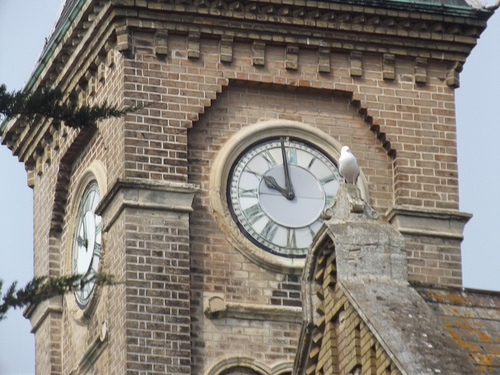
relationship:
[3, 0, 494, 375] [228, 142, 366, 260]
tower shows ten oclock on clock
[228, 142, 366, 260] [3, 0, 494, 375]
clock reads almost  on tower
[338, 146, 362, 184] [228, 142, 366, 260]
bird faces clock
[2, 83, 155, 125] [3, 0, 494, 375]
branch covers tower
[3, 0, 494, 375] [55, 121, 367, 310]
tower has 2 clocks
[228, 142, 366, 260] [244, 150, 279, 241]
clock has numbers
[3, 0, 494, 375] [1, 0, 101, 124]
tower has border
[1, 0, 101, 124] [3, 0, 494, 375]
border tops tower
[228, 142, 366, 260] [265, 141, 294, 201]
clock has hands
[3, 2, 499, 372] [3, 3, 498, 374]
scene shows building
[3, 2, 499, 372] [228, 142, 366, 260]
scene shows clock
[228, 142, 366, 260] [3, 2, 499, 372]
clock shows am in scene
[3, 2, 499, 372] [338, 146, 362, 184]
scene shows dove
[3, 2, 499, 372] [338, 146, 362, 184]
scene shows bird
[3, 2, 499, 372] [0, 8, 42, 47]
scene shows th sky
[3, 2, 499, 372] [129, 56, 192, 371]
scene shows wall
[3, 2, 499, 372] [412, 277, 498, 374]
scene shows roof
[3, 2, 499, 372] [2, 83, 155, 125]
scene suggests  tree from branch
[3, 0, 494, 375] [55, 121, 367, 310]
tower has outward facing clocks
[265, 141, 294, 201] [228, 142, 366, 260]
hands show almost  on clock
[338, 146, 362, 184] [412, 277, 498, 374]
white bird decorates roof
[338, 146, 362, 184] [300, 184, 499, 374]
white bird perched on roof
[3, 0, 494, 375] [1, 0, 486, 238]
tower has top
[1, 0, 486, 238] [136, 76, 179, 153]
top shows brick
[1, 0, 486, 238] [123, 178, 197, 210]
top shows stone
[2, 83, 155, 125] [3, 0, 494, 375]
branch extending towards tower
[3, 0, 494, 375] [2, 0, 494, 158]
tower has roof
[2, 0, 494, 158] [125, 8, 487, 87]
roof has edging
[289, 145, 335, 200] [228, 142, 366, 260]
roman numerals set inside of clock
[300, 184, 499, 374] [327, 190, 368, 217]
old church roof has tip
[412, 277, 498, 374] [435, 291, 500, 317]
roof shows shingles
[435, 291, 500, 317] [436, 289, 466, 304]
shingles have moss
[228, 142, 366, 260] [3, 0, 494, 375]
clock face set on side of tower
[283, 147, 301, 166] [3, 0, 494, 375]
xii part of clock tower